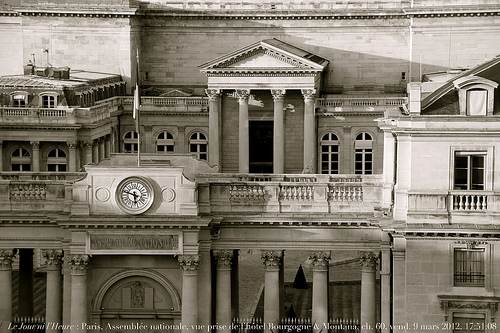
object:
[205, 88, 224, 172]
column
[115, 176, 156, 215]
clock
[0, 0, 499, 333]
building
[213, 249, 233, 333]
column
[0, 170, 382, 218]
balcony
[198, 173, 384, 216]
rail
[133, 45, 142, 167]
flag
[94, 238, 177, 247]
carving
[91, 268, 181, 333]
doorway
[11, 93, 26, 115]
window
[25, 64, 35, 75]
bucket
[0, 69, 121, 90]
roof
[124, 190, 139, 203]
hand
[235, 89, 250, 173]
pillar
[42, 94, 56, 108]
window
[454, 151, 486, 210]
window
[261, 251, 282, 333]
column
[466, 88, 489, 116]
window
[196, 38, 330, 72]
roof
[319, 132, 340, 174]
window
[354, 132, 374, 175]
window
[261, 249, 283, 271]
decoration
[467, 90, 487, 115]
curtain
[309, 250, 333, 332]
pillar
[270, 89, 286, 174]
pillar